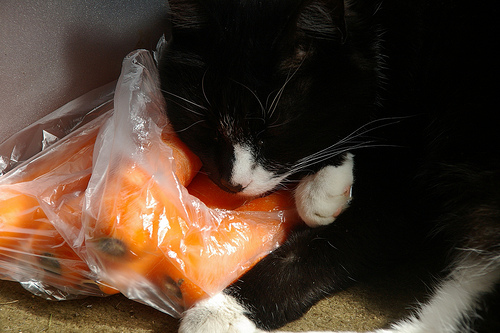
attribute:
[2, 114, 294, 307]
carrots — ripe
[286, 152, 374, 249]
paw — White cat 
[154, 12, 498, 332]
cat — Black and white , lying, sleeping, pink 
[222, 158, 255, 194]
nose — black and white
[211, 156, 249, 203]
nose — cat , Half black half white 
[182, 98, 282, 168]
wall — transparent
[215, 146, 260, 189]
nose — black 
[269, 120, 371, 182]
whiskers — long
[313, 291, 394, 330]
floor — carpeted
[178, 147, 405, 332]
legs — white 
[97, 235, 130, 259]
stem — Brown 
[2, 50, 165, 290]
produce bag — Plastic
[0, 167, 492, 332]
floor — brown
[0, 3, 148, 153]
wall — dark grey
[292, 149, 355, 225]
paw — white 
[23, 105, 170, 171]
bag — plastic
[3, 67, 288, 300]
bag — plastic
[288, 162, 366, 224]
paw — pink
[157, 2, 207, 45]
cat ear — Black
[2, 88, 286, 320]
carrots — large 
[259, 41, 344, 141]
hair — white ear